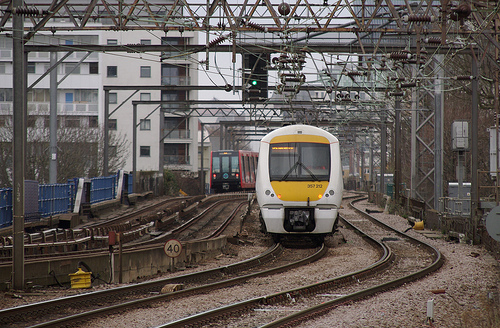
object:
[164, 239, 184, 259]
sign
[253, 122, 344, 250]
train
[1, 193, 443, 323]
railroad track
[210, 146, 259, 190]
train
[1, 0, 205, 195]
building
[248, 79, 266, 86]
train signal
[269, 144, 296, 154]
sign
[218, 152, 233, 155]
sign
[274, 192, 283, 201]
head light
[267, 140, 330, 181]
windshield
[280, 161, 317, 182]
windshield wipers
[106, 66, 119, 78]
window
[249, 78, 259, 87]
traffic light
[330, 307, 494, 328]
gravel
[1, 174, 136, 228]
fence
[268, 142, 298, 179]
window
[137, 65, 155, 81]
window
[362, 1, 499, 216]
building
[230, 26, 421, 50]
walkway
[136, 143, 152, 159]
window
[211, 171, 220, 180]
lights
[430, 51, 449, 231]
steel beam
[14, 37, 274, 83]
electric wires